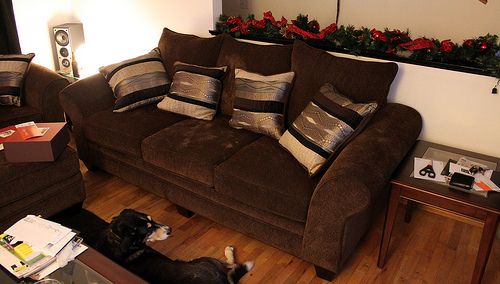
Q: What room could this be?
A: It is a living room.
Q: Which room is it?
A: It is a living room.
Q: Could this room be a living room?
A: Yes, it is a living room.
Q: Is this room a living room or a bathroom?
A: It is a living room.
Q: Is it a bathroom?
A: No, it is a living room.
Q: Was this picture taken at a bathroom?
A: No, the picture was taken in a living room.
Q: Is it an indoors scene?
A: Yes, it is indoors.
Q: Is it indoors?
A: Yes, it is indoors.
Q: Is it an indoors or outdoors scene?
A: It is indoors.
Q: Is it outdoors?
A: No, it is indoors.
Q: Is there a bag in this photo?
A: No, there are no bags.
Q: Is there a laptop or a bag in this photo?
A: No, there are no bags or laptops.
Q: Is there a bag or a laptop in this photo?
A: No, there are no bags or laptops.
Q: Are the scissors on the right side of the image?
A: Yes, the scissors are on the right of the image.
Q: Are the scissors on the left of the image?
A: No, the scissors are on the right of the image.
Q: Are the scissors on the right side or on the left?
A: The scissors are on the right of the image.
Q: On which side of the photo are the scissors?
A: The scissors are on the right of the image.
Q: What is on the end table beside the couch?
A: The scissors are on the end table.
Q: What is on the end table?
A: The scissors are on the end table.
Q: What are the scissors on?
A: The scissors are on the end table.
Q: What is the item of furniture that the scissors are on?
A: The piece of furniture is an end table.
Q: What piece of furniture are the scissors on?
A: The scissors are on the end table.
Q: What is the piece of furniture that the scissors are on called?
A: The piece of furniture is an end table.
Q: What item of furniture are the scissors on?
A: The scissors are on the end table.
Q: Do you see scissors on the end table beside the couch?
A: Yes, there are scissors on the end table.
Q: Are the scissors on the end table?
A: Yes, the scissors are on the end table.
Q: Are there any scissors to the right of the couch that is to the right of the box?
A: Yes, there are scissors to the right of the couch.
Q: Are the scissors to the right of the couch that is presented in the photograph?
A: Yes, the scissors are to the right of the couch.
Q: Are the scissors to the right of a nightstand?
A: No, the scissors are to the right of the couch.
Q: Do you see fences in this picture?
A: No, there are no fences.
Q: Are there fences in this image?
A: No, there are no fences.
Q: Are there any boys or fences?
A: No, there are no fences or boys.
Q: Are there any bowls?
A: No, there are no bowls.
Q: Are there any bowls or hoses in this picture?
A: No, there are no bowls or hoses.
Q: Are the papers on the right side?
A: Yes, the papers are on the right of the image.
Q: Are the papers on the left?
A: No, the papers are on the right of the image.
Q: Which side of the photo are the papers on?
A: The papers are on the right of the image.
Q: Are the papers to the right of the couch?
A: Yes, the papers are to the right of the couch.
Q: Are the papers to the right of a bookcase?
A: No, the papers are to the right of the couch.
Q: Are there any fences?
A: No, there are no fences.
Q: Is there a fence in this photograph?
A: No, there are no fences.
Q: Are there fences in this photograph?
A: No, there are no fences.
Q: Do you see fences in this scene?
A: No, there are no fences.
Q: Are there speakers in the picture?
A: Yes, there is a speaker.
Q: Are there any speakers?
A: Yes, there is a speaker.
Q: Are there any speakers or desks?
A: Yes, there is a speaker.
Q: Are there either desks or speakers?
A: Yes, there is a speaker.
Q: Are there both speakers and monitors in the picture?
A: No, there is a speaker but no monitors.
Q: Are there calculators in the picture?
A: No, there are no calculators.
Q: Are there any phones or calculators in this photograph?
A: No, there are no calculators or phones.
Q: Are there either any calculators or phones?
A: No, there are no calculators or phones.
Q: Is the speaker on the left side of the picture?
A: Yes, the speaker is on the left of the image.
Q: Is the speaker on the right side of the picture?
A: No, the speaker is on the left of the image.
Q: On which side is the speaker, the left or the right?
A: The speaker is on the left of the image.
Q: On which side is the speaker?
A: The speaker is on the left of the image.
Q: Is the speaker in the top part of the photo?
A: Yes, the speaker is in the top of the image.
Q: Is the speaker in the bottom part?
A: No, the speaker is in the top of the image.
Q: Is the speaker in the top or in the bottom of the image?
A: The speaker is in the top of the image.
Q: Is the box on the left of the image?
A: Yes, the box is on the left of the image.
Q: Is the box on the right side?
A: No, the box is on the left of the image.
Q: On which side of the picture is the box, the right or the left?
A: The box is on the left of the image.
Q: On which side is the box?
A: The box is on the left of the image.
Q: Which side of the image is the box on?
A: The box is on the left of the image.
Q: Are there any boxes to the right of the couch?
A: No, the box is to the left of the couch.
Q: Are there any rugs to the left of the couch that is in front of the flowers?
A: No, there is a box to the left of the couch.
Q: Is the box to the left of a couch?
A: Yes, the box is to the left of a couch.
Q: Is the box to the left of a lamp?
A: No, the box is to the left of a couch.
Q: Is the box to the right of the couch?
A: No, the box is to the left of the couch.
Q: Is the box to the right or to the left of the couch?
A: The box is to the left of the couch.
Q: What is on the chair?
A: The box is on the chair.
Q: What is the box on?
A: The box is on the chair.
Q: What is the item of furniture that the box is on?
A: The piece of furniture is a chair.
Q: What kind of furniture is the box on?
A: The box is on the chair.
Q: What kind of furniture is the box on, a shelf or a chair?
A: The box is on a chair.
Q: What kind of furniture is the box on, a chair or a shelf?
A: The box is on a chair.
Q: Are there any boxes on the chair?
A: Yes, there is a box on the chair.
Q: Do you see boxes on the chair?
A: Yes, there is a box on the chair.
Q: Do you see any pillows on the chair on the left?
A: No, there is a box on the chair.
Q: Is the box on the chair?
A: Yes, the box is on the chair.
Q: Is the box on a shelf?
A: No, the box is on the chair.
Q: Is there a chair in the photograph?
A: Yes, there is a chair.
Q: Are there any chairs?
A: Yes, there is a chair.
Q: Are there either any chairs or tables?
A: Yes, there is a chair.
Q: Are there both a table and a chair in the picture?
A: Yes, there are both a chair and a table.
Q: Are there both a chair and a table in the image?
A: Yes, there are both a chair and a table.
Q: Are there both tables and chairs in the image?
A: Yes, there are both a chair and a table.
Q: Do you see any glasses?
A: No, there are no glasses.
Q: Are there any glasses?
A: No, there are no glasses.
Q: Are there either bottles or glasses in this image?
A: No, there are no glasses or bottles.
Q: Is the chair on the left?
A: Yes, the chair is on the left of the image.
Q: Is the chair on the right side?
A: No, the chair is on the left of the image.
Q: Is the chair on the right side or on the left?
A: The chair is on the left of the image.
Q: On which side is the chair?
A: The chair is on the left of the image.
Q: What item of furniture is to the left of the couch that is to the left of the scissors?
A: The piece of furniture is a chair.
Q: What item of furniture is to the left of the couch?
A: The piece of furniture is a chair.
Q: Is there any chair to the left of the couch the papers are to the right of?
A: Yes, there is a chair to the left of the couch.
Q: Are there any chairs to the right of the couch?
A: No, the chair is to the left of the couch.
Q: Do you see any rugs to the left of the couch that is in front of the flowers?
A: No, there is a chair to the left of the couch.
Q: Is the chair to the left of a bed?
A: No, the chair is to the left of the couch.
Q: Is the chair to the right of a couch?
A: No, the chair is to the left of a couch.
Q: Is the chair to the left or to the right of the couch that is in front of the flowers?
A: The chair is to the left of the couch.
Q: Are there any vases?
A: No, there are no vases.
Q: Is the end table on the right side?
A: Yes, the end table is on the right of the image.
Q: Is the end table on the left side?
A: No, the end table is on the right of the image.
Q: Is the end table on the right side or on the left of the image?
A: The end table is on the right of the image.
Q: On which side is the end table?
A: The end table is on the right of the image.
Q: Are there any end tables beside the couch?
A: Yes, there is an end table beside the couch.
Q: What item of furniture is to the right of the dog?
A: The piece of furniture is an end table.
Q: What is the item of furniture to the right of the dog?
A: The piece of furniture is an end table.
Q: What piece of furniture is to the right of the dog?
A: The piece of furniture is an end table.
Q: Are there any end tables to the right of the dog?
A: Yes, there is an end table to the right of the dog.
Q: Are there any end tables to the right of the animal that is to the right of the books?
A: Yes, there is an end table to the right of the dog.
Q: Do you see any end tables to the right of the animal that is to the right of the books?
A: Yes, there is an end table to the right of the dog.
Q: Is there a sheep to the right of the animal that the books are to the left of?
A: No, there is an end table to the right of the dog.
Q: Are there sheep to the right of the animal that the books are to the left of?
A: No, there is an end table to the right of the dog.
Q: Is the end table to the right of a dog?
A: Yes, the end table is to the right of a dog.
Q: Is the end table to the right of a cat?
A: No, the end table is to the right of a dog.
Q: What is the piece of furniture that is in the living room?
A: The piece of furniture is an end table.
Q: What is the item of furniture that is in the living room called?
A: The piece of furniture is an end table.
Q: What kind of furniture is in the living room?
A: The piece of furniture is an end table.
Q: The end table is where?
A: The end table is in the living room.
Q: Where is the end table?
A: The end table is in the living room.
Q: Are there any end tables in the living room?
A: Yes, there is an end table in the living room.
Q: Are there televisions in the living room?
A: No, there is an end table in the living room.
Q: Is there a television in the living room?
A: No, there is an end table in the living room.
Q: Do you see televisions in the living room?
A: No, there is an end table in the living room.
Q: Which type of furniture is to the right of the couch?
A: The piece of furniture is an end table.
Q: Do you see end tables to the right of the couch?
A: Yes, there is an end table to the right of the couch.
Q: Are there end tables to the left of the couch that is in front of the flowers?
A: No, the end table is to the right of the couch.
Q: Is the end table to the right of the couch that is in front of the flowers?
A: Yes, the end table is to the right of the couch.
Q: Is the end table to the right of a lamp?
A: No, the end table is to the right of the couch.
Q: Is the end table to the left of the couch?
A: No, the end table is to the right of the couch.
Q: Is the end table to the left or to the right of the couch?
A: The end table is to the right of the couch.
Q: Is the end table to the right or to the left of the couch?
A: The end table is to the right of the couch.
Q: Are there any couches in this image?
A: Yes, there is a couch.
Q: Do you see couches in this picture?
A: Yes, there is a couch.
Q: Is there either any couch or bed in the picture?
A: Yes, there is a couch.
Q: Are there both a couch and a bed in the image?
A: No, there is a couch but no beds.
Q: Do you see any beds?
A: No, there are no beds.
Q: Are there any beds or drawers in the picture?
A: No, there are no beds or drawers.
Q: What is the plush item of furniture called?
A: The piece of furniture is a couch.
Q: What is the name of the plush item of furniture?
A: The piece of furniture is a couch.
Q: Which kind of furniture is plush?
A: The furniture is a couch.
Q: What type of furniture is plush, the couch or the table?
A: The couch is plush.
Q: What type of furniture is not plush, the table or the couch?
A: The table is not plush.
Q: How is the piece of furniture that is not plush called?
A: The piece of furniture is a table.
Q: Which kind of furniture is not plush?
A: The furniture is a table.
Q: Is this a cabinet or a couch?
A: This is a couch.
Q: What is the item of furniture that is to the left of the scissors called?
A: The piece of furniture is a couch.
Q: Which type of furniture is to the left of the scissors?
A: The piece of furniture is a couch.